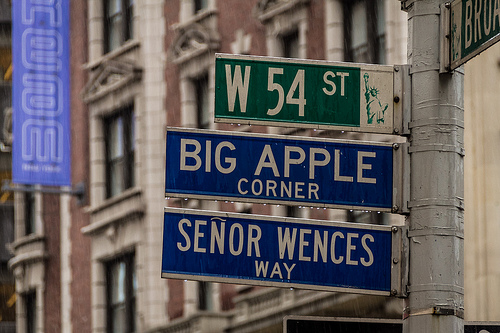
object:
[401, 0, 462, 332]
pole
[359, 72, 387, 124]
statue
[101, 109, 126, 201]
window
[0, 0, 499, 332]
building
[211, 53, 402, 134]
street sign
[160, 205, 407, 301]
sign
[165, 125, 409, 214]
sign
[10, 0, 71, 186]
banner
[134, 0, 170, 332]
post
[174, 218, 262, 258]
font